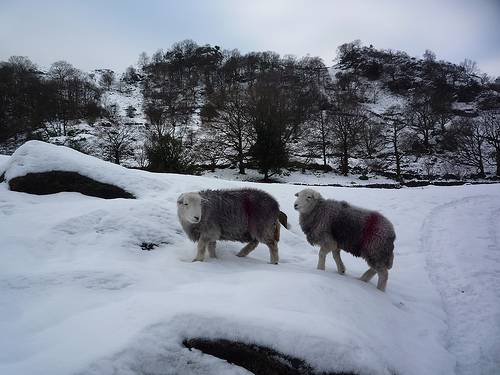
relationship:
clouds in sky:
[0, 0, 498, 82] [28, 8, 434, 44]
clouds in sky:
[0, 0, 498, 82] [2, 0, 499, 82]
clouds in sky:
[0, 0, 498, 82] [2, 4, 492, 94]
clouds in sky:
[2, 2, 498, 82] [2, 3, 499, 75]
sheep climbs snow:
[177, 187, 396, 292] [0, 51, 500, 375]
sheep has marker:
[177, 187, 396, 292] [364, 212, 378, 247]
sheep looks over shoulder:
[177, 187, 396, 292] [200, 191, 218, 212]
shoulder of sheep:
[200, 191, 218, 212] [177, 187, 396, 292]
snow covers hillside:
[3, 82, 498, 372] [17, 94, 499, 374]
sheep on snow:
[177, 187, 396, 292] [57, 245, 476, 347]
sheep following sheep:
[293, 171, 399, 292] [177, 187, 396, 292]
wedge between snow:
[191, 332, 313, 373] [114, 311, 384, 373]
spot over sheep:
[241, 193, 255, 231] [177, 187, 396, 292]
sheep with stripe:
[177, 187, 396, 292] [354, 206, 381, 250]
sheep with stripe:
[177, 187, 396, 292] [221, 192, 254, 236]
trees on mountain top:
[2, 31, 497, 182] [2, 140, 496, 370]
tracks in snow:
[432, 183, 496, 365] [0, 141, 495, 373]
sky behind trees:
[47, 2, 467, 42] [124, 36, 492, 170]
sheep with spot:
[177, 187, 396, 292] [356, 210, 381, 256]